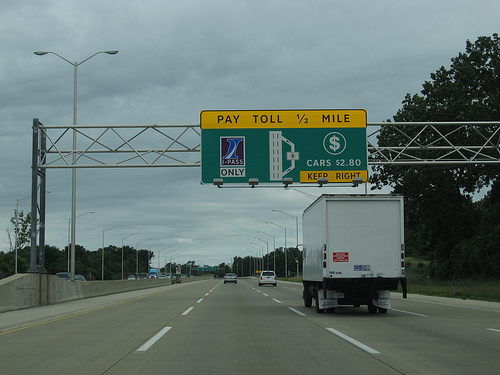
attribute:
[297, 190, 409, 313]
truck — large, white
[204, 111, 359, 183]
sign — large, green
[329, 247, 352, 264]
sign — red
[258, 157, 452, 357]
truck — white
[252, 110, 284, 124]
writing — black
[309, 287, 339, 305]
wheel — edge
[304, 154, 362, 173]
writing — white